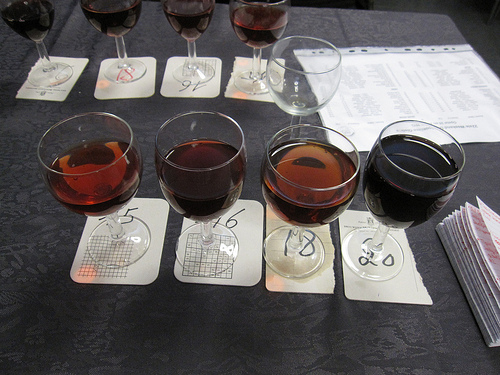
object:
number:
[278, 225, 319, 259]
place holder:
[68, 195, 168, 285]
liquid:
[46, 135, 141, 218]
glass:
[261, 123, 363, 284]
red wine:
[370, 133, 462, 196]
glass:
[261, 34, 346, 137]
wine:
[154, 134, 244, 224]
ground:
[0, 0, 499, 327]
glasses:
[158, 0, 219, 87]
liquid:
[259, 136, 361, 228]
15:
[98, 204, 140, 228]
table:
[1, 0, 498, 373]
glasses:
[2, 0, 75, 91]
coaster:
[336, 206, 433, 306]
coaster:
[263, 200, 335, 297]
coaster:
[171, 196, 266, 288]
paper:
[289, 43, 497, 153]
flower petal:
[339, 111, 467, 293]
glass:
[33, 107, 154, 271]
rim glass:
[36, 110, 137, 178]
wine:
[80, 0, 144, 38]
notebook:
[435, 193, 499, 348]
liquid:
[363, 133, 457, 229]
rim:
[378, 119, 466, 180]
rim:
[266, 123, 363, 191]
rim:
[151, 110, 248, 173]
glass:
[156, 110, 249, 275]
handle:
[116, 35, 128, 69]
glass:
[80, 0, 151, 85]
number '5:
[116, 202, 138, 226]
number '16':
[208, 203, 248, 229]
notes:
[475, 196, 499, 257]